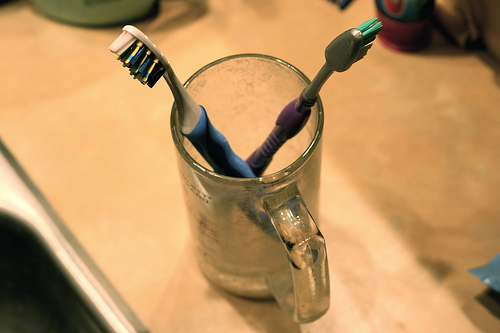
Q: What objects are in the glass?
A: Toothbrushes.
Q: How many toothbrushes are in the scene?
A: Two.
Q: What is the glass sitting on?
A: Countertop.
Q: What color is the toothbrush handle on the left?
A: Blue.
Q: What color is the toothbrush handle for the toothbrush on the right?
A: Purple.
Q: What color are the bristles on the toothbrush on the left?
A: Blue and white.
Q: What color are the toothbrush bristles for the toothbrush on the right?
A: Green.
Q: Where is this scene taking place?
A: At a sink.